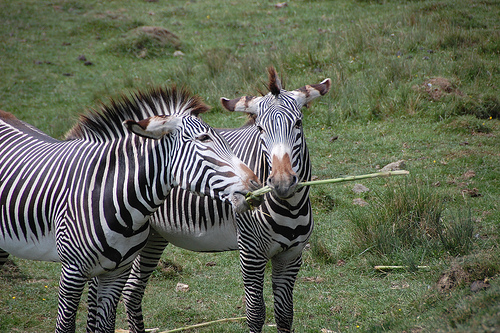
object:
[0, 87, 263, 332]
zebra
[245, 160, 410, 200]
branch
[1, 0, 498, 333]
field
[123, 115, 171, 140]
ear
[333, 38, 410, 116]
grass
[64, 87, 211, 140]
mane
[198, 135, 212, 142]
eye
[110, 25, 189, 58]
rock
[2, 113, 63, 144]
stripes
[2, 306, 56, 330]
grass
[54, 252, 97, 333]
leg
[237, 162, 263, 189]
nose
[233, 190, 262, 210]
mouth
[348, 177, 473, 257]
grass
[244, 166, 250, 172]
brown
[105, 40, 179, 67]
grass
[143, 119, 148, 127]
brown